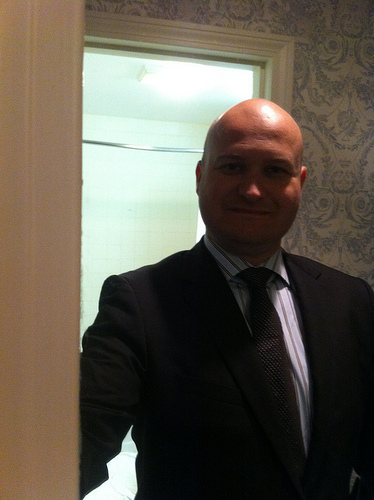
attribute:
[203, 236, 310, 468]
shirt — striped, grey, white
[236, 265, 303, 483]
tie — dark, black, white, brown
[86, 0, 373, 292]
wallpaper — purple, white, gray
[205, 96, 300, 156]
head — bald, shiny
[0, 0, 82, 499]
door — white, open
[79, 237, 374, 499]
jacket — black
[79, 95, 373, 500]
man — smiling, bald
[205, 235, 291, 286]
collar — grey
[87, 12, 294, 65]
frame — white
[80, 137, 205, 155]
rod — metal